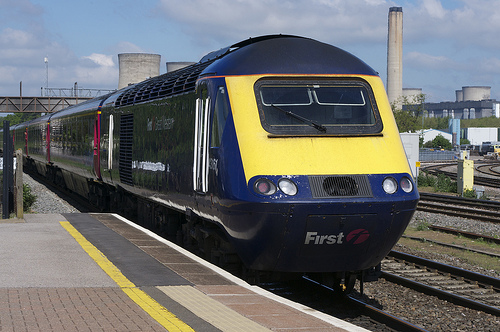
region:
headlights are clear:
[381, 177, 403, 199]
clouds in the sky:
[422, 7, 476, 34]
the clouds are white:
[419, 4, 490, 41]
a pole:
[11, 149, 40, 214]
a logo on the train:
[298, 231, 373, 246]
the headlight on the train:
[278, 178, 303, 196]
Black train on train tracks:
[0, 29, 420, 285]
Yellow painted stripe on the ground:
[57, 215, 197, 330]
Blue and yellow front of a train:
[195, 42, 421, 282]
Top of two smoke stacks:
[115, 49, 199, 89]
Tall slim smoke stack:
[384, 6, 406, 117]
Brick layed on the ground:
[1, 283, 161, 328]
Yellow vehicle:
[485, 142, 499, 154]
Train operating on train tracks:
[2, 34, 419, 296]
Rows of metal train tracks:
[346, 183, 498, 330]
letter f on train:
[301, 226, 313, 246]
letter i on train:
[312, 233, 318, 243]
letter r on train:
[320, 230, 326, 245]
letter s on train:
[325, 230, 335, 246]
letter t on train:
[336, 227, 344, 247]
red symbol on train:
[347, 221, 369, 248]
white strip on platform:
[228, 270, 253, 293]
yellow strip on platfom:
[125, 282, 152, 315]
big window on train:
[262, 79, 366, 132]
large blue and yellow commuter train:
[198, 48, 432, 258]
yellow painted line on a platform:
[49, 214, 165, 329]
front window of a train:
[248, 80, 378, 136]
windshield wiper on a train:
[261, 93, 327, 130]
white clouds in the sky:
[14, 31, 101, 66]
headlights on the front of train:
[249, 170, 412, 201]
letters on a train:
[304, 220, 371, 253]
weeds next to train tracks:
[420, 216, 490, 246]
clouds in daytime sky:
[0, 1, 499, 97]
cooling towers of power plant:
[116, 52, 196, 87]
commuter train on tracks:
[4, 34, 416, 329]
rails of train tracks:
[341, 203, 498, 328]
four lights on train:
[255, 174, 415, 197]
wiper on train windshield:
[254, 75, 381, 142]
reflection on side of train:
[10, 70, 226, 217]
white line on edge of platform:
[3, 210, 373, 329]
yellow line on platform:
[59, 218, 191, 330]